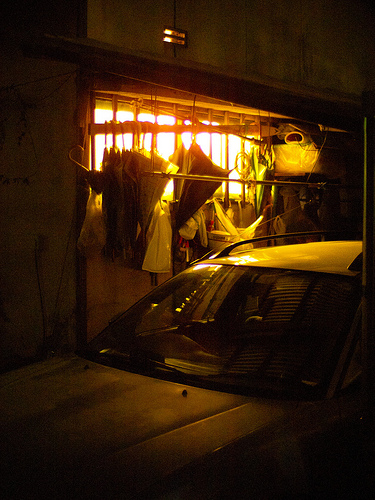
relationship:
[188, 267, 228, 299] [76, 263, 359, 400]
reflection in screen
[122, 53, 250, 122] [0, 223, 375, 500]
line in automobile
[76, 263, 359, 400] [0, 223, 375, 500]
screen of automobile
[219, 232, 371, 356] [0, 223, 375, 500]
bonnet of automobile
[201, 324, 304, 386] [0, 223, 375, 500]
wipers of automobile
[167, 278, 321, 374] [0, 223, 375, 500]
screen of automobile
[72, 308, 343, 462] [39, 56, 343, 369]
automobile in garage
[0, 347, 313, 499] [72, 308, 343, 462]
bonnet on automobile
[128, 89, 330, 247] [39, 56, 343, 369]
window of garage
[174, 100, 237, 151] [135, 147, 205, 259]
handle on umbrella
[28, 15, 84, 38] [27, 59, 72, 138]
vent in wall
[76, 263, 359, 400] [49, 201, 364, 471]
screen on car